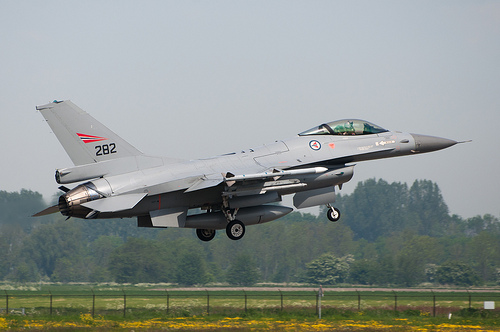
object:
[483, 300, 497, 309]
sign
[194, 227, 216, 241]
wheel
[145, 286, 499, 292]
runway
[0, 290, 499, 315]
fence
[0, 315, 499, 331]
field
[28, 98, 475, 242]
airplane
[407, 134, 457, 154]
nose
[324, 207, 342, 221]
wheel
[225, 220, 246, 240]
wheel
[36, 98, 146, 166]
wing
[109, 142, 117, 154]
number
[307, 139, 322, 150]
decal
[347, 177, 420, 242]
trees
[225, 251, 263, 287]
tree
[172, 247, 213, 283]
tree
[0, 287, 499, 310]
field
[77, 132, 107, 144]
logo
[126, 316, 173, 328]
patch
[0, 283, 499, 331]
grass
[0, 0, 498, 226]
sky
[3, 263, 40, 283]
tree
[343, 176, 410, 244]
tree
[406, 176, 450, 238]
tree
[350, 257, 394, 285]
tree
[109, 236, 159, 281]
tree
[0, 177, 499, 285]
forest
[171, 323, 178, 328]
flowers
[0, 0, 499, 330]
airport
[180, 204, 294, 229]
missiles